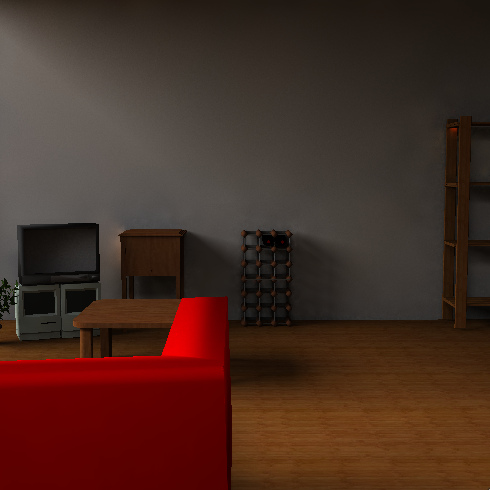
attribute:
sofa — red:
[1, 290, 236, 486]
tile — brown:
[237, 312, 486, 487]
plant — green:
[1, 277, 19, 326]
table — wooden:
[47, 261, 252, 377]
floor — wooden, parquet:
[1, 319, 487, 489]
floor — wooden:
[228, 317, 487, 488]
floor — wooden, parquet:
[269, 341, 484, 488]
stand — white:
[13, 287, 99, 348]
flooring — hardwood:
[245, 324, 485, 465]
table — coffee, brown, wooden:
[71, 291, 184, 355]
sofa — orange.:
[16, 330, 240, 395]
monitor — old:
[12, 283, 62, 341]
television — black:
[16, 213, 134, 311]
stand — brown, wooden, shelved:
[439, 111, 488, 333]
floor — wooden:
[255, 333, 455, 463]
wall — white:
[0, 0, 490, 322]